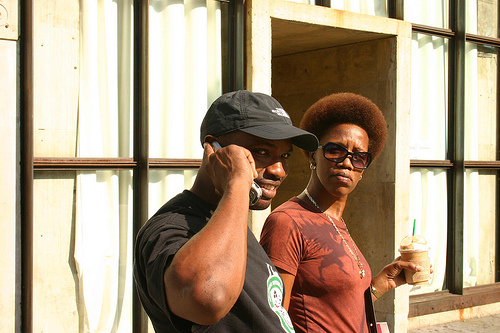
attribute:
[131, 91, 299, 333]
person — talking, looking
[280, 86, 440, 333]
woman — looking, gold hoop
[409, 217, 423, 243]
straw — green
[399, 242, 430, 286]
drink — brown, coffee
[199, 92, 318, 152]
hat — black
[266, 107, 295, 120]
logo — white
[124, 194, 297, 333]
shirt — black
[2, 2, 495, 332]
day — sunny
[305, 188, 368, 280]
necklace — silver